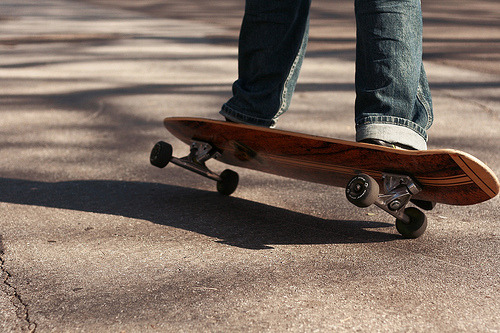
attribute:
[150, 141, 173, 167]
wheel — black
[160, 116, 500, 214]
skateboard — brown, tilted, black, wood patterned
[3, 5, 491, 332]
street — concrete, light gray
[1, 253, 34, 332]
crack — small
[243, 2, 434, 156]
jeans — blue, folded, dark blue, denim, rolled up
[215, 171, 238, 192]
wheel — black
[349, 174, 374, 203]
wheel — black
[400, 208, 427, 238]
wheel — black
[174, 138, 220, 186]
axle — metal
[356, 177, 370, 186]
writing — wheel